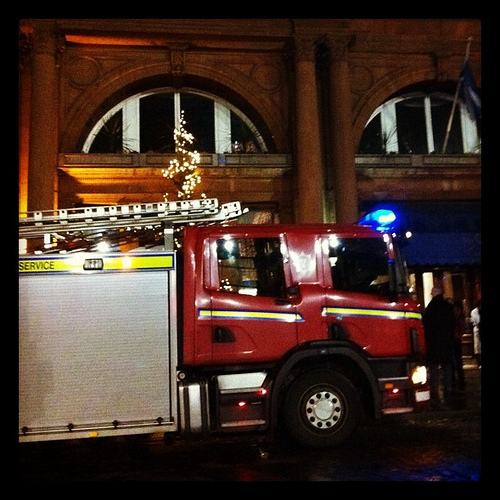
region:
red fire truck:
[19, 188, 433, 468]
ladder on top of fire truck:
[20, 188, 274, 259]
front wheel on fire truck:
[275, 358, 389, 455]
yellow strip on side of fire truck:
[18, 258, 175, 276]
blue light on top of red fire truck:
[350, 208, 402, 231]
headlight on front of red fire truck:
[406, 363, 436, 393]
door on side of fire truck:
[203, 285, 303, 360]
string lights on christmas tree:
[150, 102, 217, 202]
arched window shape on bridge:
[70, 80, 265, 157]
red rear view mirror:
[280, 273, 310, 313]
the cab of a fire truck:
[178, 203, 432, 455]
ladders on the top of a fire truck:
[15, 192, 256, 240]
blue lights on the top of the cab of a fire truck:
[359, 199, 406, 237]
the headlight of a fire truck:
[408, 358, 430, 394]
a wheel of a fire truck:
[279, 355, 364, 462]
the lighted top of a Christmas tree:
[157, 104, 207, 199]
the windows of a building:
[354, 77, 494, 162]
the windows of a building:
[72, 70, 279, 162]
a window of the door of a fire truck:
[324, 229, 401, 306]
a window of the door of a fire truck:
[208, 228, 298, 315]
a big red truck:
[183, 194, 465, 451]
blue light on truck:
[363, 203, 402, 232]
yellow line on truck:
[23, 252, 180, 284]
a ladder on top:
[27, 179, 257, 251]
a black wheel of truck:
[264, 351, 383, 471]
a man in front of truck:
[411, 272, 496, 474]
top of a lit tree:
[148, 107, 215, 200]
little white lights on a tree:
[136, 94, 221, 208]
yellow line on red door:
[191, 287, 328, 334]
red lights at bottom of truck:
[221, 377, 406, 424]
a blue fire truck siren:
[346, 195, 398, 235]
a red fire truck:
[17, 202, 437, 450]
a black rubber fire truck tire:
[281, 360, 365, 453]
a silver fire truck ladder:
[4, 190, 252, 236]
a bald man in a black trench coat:
[423, 282, 458, 411]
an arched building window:
[68, 72, 275, 167]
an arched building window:
[352, 60, 490, 166]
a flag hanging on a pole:
[449, 44, 492, 141]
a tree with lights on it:
[163, 102, 218, 207]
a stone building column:
[23, 15, 68, 263]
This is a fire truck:
[24, 208, 455, 467]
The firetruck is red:
[17, 196, 447, 461]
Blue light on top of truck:
[348, 194, 403, 238]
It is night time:
[12, 17, 484, 487]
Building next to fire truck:
[20, 19, 482, 211]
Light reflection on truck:
[57, 232, 144, 282]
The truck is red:
[134, 198, 425, 456]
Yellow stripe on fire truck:
[189, 294, 436, 334]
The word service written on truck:
[17, 258, 63, 278]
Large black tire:
[259, 356, 396, 481]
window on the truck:
[217, 245, 276, 302]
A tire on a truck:
[284, 367, 369, 455]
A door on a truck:
[201, 230, 297, 357]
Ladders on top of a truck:
[16, 196, 247, 239]